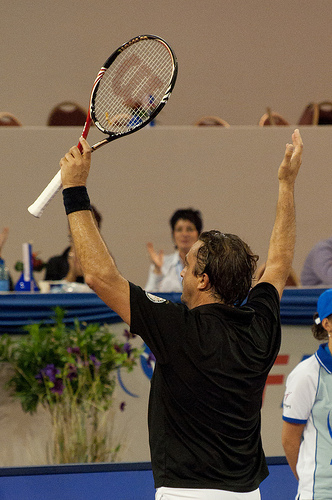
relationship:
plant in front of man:
[4, 305, 151, 472] [55, 125, 305, 498]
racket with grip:
[29, 36, 176, 220] [20, 167, 63, 220]